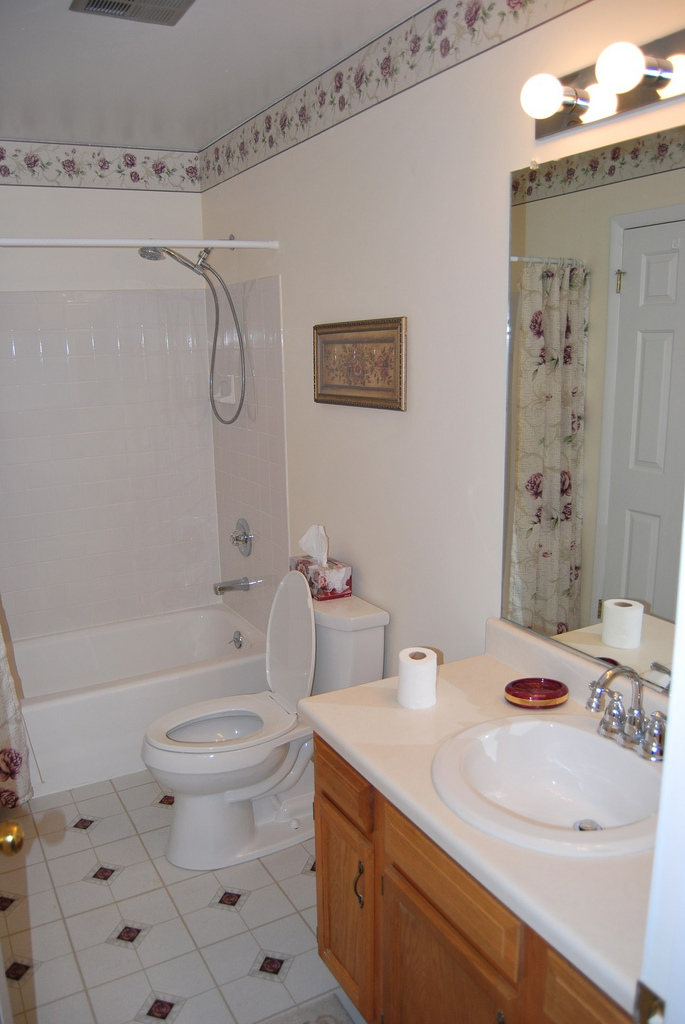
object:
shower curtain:
[510, 266, 587, 629]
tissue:
[290, 521, 350, 598]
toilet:
[136, 581, 377, 871]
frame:
[300, 315, 408, 417]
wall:
[0, 159, 502, 610]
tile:
[50, 845, 161, 908]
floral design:
[292, 555, 350, 602]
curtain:
[509, 254, 595, 631]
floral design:
[521, 307, 575, 370]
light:
[593, 41, 651, 98]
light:
[517, 69, 569, 120]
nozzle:
[139, 242, 165, 261]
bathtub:
[6, 595, 266, 781]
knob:
[0, 813, 23, 859]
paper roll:
[393, 644, 440, 712]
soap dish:
[500, 675, 571, 712]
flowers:
[292, 559, 353, 600]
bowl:
[503, 677, 571, 708]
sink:
[444, 712, 663, 845]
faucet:
[583, 663, 662, 760]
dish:
[500, 674, 570, 709]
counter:
[331, 652, 660, 992]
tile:
[64, 889, 199, 991]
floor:
[0, 789, 351, 1022]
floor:
[0, 803, 307, 1024]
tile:
[187, 860, 287, 940]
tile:
[210, 913, 330, 1008]